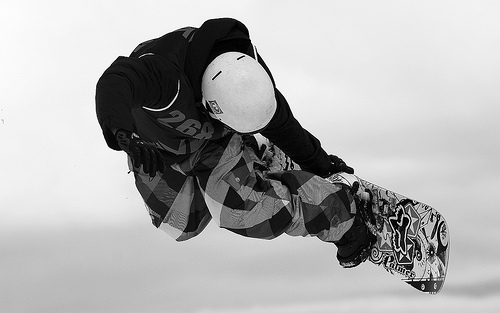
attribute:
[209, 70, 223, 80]
space — black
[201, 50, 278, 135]
helmet — white, hard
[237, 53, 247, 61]
space — black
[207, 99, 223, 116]
sticker — square, logo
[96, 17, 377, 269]
person — snowboarder, man, leaning, looking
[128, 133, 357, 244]
pants — checkered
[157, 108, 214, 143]
number — 268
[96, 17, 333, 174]
coat — dark, hooded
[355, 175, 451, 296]
board — busy, used, graffitied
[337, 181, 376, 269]
boot — black, dark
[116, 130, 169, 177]
glove — black, padded, two-toned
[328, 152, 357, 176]
glove — black, padded, two-toned